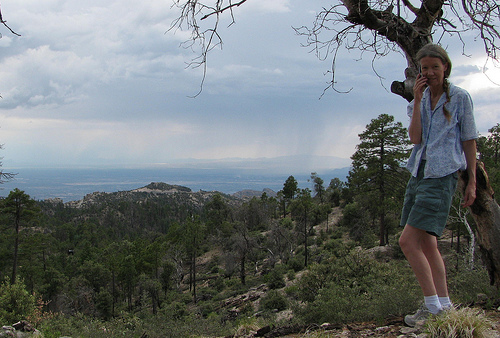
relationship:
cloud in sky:
[2, 41, 145, 106] [257, 115, 335, 149]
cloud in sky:
[0, 0, 500, 129] [257, 115, 335, 149]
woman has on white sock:
[402, 47, 476, 318] [438, 294, 452, 308]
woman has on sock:
[402, 47, 476, 318] [422, 294, 444, 314]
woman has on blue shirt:
[397, 42, 476, 326] [403, 82, 475, 178]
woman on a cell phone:
[397, 42, 476, 326] [415, 66, 427, 83]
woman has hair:
[397, 42, 476, 326] [416, 43, 451, 126]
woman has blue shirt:
[402, 47, 476, 318] [429, 92, 469, 169]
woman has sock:
[402, 47, 476, 318] [422, 294, 444, 314]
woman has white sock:
[402, 47, 476, 318] [438, 294, 452, 308]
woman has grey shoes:
[397, 42, 476, 326] [407, 300, 459, 327]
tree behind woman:
[171, 0, 496, 285] [397, 42, 476, 326]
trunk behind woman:
[396, 49, 498, 301] [397, 42, 476, 326]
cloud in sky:
[0, 0, 500, 129] [242, 19, 297, 126]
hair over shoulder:
[416, 43, 457, 128] [424, 84, 474, 111]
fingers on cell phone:
[413, 73, 428, 92] [416, 61, 425, 81]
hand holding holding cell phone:
[393, 66, 456, 140] [416, 63, 426, 77]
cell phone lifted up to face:
[416, 61, 425, 81] [400, 50, 450, 115]